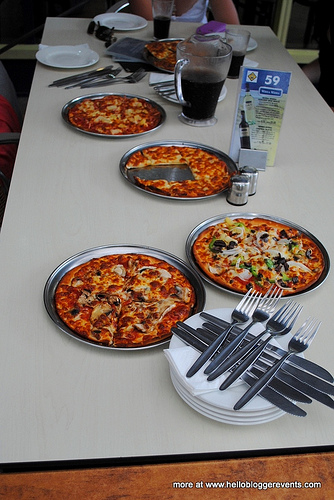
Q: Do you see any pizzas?
A: Yes, there is a pizza.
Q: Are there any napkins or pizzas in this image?
A: Yes, there is a pizza.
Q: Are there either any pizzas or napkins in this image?
A: Yes, there is a pizza.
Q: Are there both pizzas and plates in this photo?
A: Yes, there are both a pizza and a plate.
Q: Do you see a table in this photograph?
A: Yes, there is a table.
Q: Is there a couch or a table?
A: Yes, there is a table.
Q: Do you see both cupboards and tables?
A: No, there is a table but no cupboards.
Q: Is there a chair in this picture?
A: No, there are no chairs.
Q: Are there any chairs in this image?
A: No, there are no chairs.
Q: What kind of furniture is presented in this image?
A: The furniture is a table.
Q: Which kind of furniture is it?
A: The piece of furniture is a table.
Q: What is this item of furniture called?
A: This is a table.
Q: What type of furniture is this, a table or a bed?
A: This is a table.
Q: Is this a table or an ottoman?
A: This is a table.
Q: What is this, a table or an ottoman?
A: This is a table.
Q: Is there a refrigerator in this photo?
A: No, there are no refrigerators.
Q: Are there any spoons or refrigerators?
A: No, there are no refrigerators or spoons.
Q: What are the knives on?
A: The knives are on the table.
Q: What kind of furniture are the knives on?
A: The knives are on the table.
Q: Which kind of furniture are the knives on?
A: The knives are on the table.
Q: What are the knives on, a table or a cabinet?
A: The knives are on a table.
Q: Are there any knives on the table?
A: Yes, there are knives on the table.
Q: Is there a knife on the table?
A: Yes, there are knives on the table.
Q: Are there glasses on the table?
A: No, there are knives on the table.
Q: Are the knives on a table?
A: Yes, the knives are on a table.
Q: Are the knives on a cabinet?
A: No, the knives are on a table.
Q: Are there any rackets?
A: No, there are no rackets.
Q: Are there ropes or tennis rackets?
A: No, there are no tennis rackets or ropes.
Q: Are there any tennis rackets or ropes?
A: No, there are no tennis rackets or ropes.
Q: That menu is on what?
A: The menu is on the table.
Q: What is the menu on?
A: The menu is on the table.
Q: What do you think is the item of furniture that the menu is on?
A: The piece of furniture is a table.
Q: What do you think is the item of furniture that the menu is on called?
A: The piece of furniture is a table.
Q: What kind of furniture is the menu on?
A: The menu is on the table.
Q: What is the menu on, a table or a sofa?
A: The menu is on a table.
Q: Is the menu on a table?
A: Yes, the menu is on a table.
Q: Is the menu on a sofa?
A: No, the menu is on a table.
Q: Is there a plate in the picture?
A: Yes, there is a plate.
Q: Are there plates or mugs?
A: Yes, there is a plate.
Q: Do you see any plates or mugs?
A: Yes, there is a plate.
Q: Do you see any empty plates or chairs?
A: Yes, there is an empty plate.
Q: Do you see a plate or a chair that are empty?
A: Yes, the plate is empty.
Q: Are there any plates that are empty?
A: Yes, there is an empty plate.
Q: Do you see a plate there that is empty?
A: Yes, there is a plate that is empty.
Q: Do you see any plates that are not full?
A: Yes, there is a empty plate.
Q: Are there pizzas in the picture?
A: Yes, there is a pizza.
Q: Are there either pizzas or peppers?
A: Yes, there is a pizza.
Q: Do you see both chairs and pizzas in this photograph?
A: No, there is a pizza but no chairs.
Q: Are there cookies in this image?
A: No, there are no cookies.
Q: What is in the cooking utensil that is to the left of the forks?
A: The pizza is in the pan.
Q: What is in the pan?
A: The pizza is in the pan.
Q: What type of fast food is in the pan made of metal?
A: The food is a pizza.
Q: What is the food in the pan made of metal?
A: The food is a pizza.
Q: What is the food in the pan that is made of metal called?
A: The food is a pizza.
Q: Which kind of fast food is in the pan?
A: The food is a pizza.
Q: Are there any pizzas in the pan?
A: Yes, there is a pizza in the pan.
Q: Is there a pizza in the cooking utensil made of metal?
A: Yes, there is a pizza in the pan.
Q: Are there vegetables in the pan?
A: No, there is a pizza in the pan.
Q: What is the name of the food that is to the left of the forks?
A: The food is a pizza.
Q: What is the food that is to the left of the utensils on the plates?
A: The food is a pizza.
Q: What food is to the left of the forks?
A: The food is a pizza.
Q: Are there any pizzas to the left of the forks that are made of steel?
A: Yes, there is a pizza to the left of the forks.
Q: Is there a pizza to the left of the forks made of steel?
A: Yes, there is a pizza to the left of the forks.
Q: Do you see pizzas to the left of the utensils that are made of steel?
A: Yes, there is a pizza to the left of the forks.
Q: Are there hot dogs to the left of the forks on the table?
A: No, there is a pizza to the left of the forks.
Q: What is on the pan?
A: The pizza is on the pan.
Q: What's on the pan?
A: The pizza is on the pan.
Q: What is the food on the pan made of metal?
A: The food is a pizza.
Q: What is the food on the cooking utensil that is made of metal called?
A: The food is a pizza.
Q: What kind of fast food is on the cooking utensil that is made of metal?
A: The food is a pizza.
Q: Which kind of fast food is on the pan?
A: The food is a pizza.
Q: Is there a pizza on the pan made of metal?
A: Yes, there is a pizza on the pan.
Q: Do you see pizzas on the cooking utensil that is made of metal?
A: Yes, there is a pizza on the pan.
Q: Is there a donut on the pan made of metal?
A: No, there is a pizza on the pan.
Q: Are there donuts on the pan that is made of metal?
A: No, there is a pizza on the pan.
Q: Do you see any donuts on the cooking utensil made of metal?
A: No, there is a pizza on the pan.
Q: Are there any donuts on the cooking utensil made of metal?
A: No, there is a pizza on the pan.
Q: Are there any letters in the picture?
A: Yes, there are letters.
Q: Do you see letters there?
A: Yes, there are letters.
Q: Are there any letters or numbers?
A: Yes, there are letters.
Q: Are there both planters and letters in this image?
A: No, there are letters but no planters.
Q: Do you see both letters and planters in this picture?
A: No, there are letters but no planters.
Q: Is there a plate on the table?
A: Yes, there are plates on the table.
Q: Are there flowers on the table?
A: No, there are plates on the table.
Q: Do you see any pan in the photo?
A: Yes, there is a pan.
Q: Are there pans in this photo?
A: Yes, there is a pan.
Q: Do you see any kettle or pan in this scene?
A: Yes, there is a pan.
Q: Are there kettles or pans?
A: Yes, there is a pan.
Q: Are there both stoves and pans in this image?
A: No, there is a pan but no stoves.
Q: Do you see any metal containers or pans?
A: Yes, there is a metal pan.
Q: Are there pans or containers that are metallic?
A: Yes, the pan is metallic.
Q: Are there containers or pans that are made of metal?
A: Yes, the pan is made of metal.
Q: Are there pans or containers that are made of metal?
A: Yes, the pan is made of metal.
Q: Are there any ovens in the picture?
A: No, there are no ovens.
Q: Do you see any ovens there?
A: No, there are no ovens.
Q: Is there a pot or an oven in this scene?
A: No, there are no ovens or pots.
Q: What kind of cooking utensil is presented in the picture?
A: The cooking utensil is a pan.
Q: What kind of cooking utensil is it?
A: The cooking utensil is a pan.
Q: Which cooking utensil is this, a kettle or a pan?
A: That is a pan.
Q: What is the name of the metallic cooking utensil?
A: The cooking utensil is a pan.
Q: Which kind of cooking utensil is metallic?
A: The cooking utensil is a pan.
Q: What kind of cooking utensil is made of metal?
A: The cooking utensil is a pan.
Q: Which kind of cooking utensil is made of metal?
A: The cooking utensil is a pan.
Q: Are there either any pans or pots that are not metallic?
A: No, there is a pan but it is metallic.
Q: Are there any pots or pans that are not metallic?
A: No, there is a pan but it is metallic.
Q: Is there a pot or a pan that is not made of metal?
A: No, there is a pan but it is made of metal.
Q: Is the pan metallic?
A: Yes, the pan is metallic.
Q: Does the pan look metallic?
A: Yes, the pan is metallic.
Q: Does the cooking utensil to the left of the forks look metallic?
A: Yes, the pan is metallic.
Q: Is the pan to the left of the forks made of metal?
A: Yes, the pan is made of metal.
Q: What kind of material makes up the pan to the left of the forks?
A: The pan is made of metal.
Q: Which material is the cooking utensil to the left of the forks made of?
A: The pan is made of metal.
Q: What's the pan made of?
A: The pan is made of metal.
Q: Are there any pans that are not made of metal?
A: No, there is a pan but it is made of metal.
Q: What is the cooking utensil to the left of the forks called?
A: The cooking utensil is a pan.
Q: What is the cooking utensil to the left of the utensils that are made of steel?
A: The cooking utensil is a pan.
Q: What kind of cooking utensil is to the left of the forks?
A: The cooking utensil is a pan.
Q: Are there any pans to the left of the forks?
A: Yes, there is a pan to the left of the forks.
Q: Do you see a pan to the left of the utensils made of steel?
A: Yes, there is a pan to the left of the forks.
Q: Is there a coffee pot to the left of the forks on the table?
A: No, there is a pan to the left of the forks.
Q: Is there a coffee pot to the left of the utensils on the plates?
A: No, there is a pan to the left of the forks.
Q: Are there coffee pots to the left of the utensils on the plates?
A: No, there is a pan to the left of the forks.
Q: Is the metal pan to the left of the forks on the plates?
A: Yes, the pan is to the left of the forks.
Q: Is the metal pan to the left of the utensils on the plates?
A: Yes, the pan is to the left of the forks.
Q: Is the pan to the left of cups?
A: No, the pan is to the left of the forks.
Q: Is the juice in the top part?
A: Yes, the juice is in the top of the image.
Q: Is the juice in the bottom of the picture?
A: No, the juice is in the top of the image.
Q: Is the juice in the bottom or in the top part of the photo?
A: The juice is in the top of the image.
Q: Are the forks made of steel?
A: Yes, the forks are made of steel.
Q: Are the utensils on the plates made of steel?
A: Yes, the forks are made of steel.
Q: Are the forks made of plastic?
A: No, the forks are made of steel.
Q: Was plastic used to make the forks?
A: No, the forks are made of steel.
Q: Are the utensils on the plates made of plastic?
A: No, the forks are made of steel.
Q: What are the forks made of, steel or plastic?
A: The forks are made of steel.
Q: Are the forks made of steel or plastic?
A: The forks are made of steel.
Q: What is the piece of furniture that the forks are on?
A: The piece of furniture is a table.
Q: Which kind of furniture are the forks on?
A: The forks are on the table.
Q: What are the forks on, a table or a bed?
A: The forks are on a table.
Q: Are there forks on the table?
A: Yes, there are forks on the table.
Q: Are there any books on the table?
A: No, there are forks on the table.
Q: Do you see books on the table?
A: No, there are forks on the table.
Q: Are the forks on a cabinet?
A: No, the forks are on the table.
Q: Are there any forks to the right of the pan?
A: Yes, there are forks to the right of the pan.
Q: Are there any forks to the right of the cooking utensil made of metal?
A: Yes, there are forks to the right of the pan.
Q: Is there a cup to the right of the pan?
A: No, there are forks to the right of the pan.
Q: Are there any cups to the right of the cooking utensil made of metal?
A: No, there are forks to the right of the pan.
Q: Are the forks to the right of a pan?
A: Yes, the forks are to the right of a pan.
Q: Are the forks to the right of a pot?
A: No, the forks are to the right of a pan.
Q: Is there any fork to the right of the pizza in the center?
A: Yes, there are forks to the right of the pizza.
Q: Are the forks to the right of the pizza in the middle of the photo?
A: Yes, the forks are to the right of the pizza.